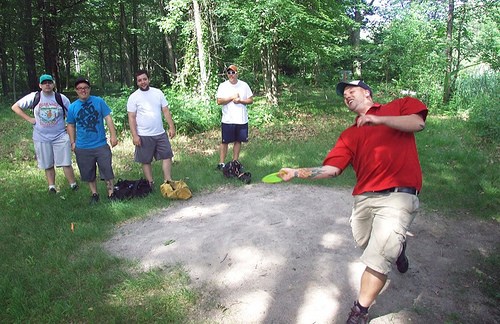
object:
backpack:
[113, 176, 152, 200]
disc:
[262, 171, 285, 182]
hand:
[277, 168, 294, 182]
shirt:
[15, 91, 71, 142]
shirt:
[66, 96, 112, 150]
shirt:
[127, 87, 169, 137]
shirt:
[216, 79, 253, 125]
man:
[216, 65, 253, 171]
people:
[11, 65, 425, 324]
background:
[0, 0, 500, 217]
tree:
[157, 0, 230, 118]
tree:
[357, 0, 434, 95]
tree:
[433, 0, 489, 111]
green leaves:
[0, 2, 497, 133]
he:
[67, 78, 118, 204]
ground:
[106, 181, 500, 324]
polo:
[322, 97, 427, 195]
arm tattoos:
[294, 168, 337, 179]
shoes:
[343, 240, 408, 323]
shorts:
[73, 144, 115, 182]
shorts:
[33, 133, 71, 169]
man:
[11, 74, 79, 195]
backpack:
[32, 91, 68, 120]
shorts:
[348, 191, 420, 277]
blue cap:
[40, 74, 54, 84]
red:
[364, 136, 391, 168]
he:
[275, 81, 425, 324]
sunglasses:
[228, 71, 236, 74]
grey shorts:
[134, 132, 174, 164]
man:
[126, 70, 176, 192]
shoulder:
[28, 92, 69, 105]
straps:
[33, 91, 64, 107]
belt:
[371, 187, 419, 195]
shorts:
[221, 122, 249, 143]